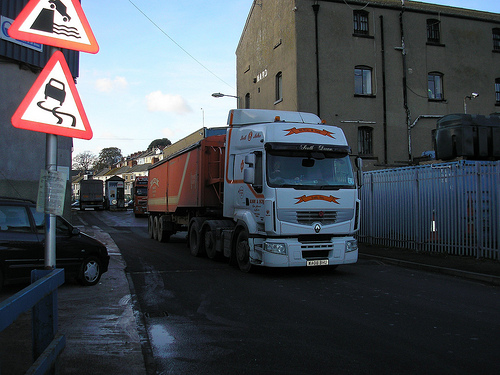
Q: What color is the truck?
A: Red and white.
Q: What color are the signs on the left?
A: Red, white, and black.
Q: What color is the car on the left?
A: Black.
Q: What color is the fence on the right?
A: White.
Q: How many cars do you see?
A: One.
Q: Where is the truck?
A: On the street.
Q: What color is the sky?
A: Blue.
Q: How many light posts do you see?
A: 1.